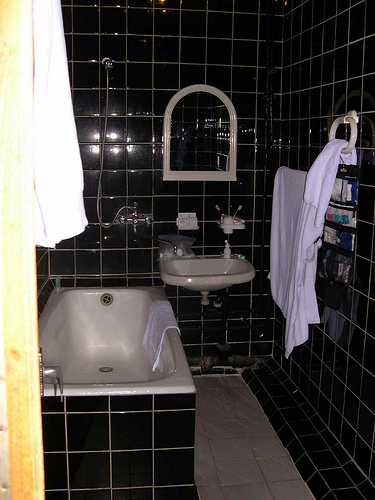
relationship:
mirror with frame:
[160, 81, 239, 182] [160, 83, 237, 181]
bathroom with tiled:
[0, 5, 362, 493] [62, 3, 157, 282]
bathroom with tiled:
[0, 5, 362, 493] [181, 5, 374, 84]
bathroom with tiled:
[0, 5, 362, 493] [237, 91, 272, 336]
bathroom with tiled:
[0, 5, 362, 493] [278, 316, 371, 497]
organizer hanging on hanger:
[309, 150, 365, 315] [325, 112, 360, 154]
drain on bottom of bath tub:
[96, 365, 114, 376] [35, 277, 191, 398]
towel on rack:
[267, 165, 324, 358] [274, 164, 329, 187]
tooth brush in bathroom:
[224, 195, 253, 233] [0, 5, 362, 493]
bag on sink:
[154, 232, 199, 259] [158, 246, 256, 301]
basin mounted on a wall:
[187, 256, 247, 297] [63, 1, 279, 373]